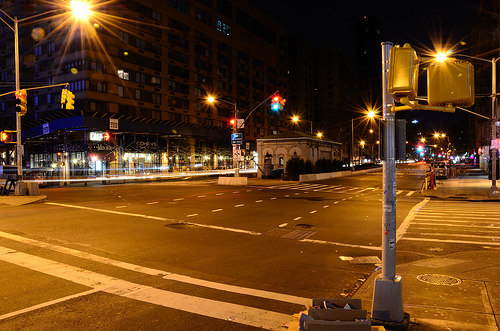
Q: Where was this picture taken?
A: A city street.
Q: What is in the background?
A: Buildings.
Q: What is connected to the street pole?
A: Signal lights.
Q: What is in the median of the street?
A: Building.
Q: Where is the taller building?
A: Left of photo.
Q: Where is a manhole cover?
A: Nearest corner.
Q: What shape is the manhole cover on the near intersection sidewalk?
A: Round.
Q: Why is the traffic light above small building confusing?
A: It is red and green simultaneously.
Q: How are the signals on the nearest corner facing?
A: Away from camera.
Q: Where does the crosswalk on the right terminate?
A: Curb across street.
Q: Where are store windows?
A: Far corner.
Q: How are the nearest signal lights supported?
A: Metal post.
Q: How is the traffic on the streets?
A: Clear.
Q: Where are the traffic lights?
A: On metal poles beside the curb.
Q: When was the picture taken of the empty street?
A: Late night.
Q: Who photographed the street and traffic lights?
A: A man exploring the city.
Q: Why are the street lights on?
A: Dark outside.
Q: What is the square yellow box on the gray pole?
A: Crosswalk sign.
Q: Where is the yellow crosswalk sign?
A: Sidewalk on a grey pole.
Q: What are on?
A: Lights.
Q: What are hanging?
A: Traffic lights.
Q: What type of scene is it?
A: Outdoor.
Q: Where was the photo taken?
A: Street.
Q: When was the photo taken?
A: Nighttime.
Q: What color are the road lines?
A: White.